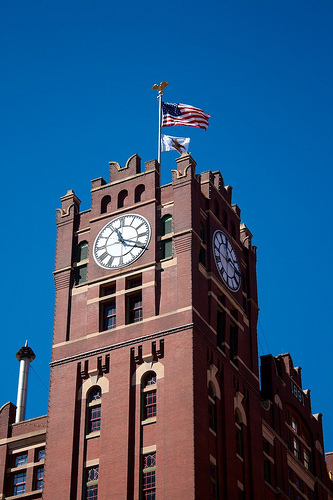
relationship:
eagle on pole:
[135, 70, 176, 103] [142, 58, 164, 200]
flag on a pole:
[152, 95, 220, 128] [143, 81, 171, 160]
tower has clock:
[43, 151, 280, 377] [208, 221, 257, 282]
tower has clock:
[43, 151, 280, 377] [83, 213, 161, 274]